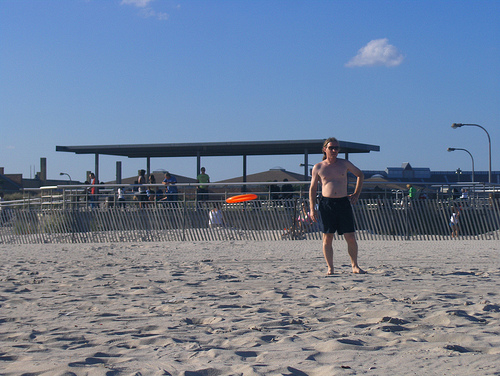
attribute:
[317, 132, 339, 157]
hair — blonde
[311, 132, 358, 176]
man — barefoot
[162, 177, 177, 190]
shirt — blue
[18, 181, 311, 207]
railing — silver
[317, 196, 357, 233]
trunks — swim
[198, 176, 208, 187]
shirt — green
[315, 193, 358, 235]
shorts — black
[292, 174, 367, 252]
shorts — black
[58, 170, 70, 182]
pole — light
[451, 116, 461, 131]
lamp — street